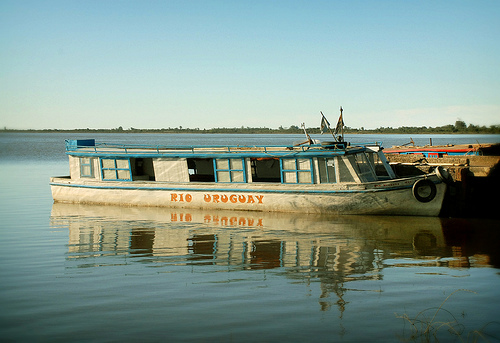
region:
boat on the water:
[40, 111, 460, 236]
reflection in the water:
[58, 202, 374, 289]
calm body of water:
[1, 133, 498, 340]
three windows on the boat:
[122, 153, 285, 186]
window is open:
[98, 158, 163, 182]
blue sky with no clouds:
[1, 1, 499, 128]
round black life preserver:
[410, 173, 446, 209]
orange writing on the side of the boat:
[169, 191, 271, 210]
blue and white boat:
[39, 121, 454, 224]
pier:
[354, 129, 499, 214]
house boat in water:
[4, 147, 435, 223]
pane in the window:
[101, 167, 117, 180]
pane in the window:
[116, 170, 131, 182]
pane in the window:
[116, 158, 130, 169]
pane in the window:
[103, 158, 119, 170]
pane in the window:
[216, 171, 230, 184]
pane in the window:
[213, 159, 227, 171]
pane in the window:
[231, 170, 247, 187]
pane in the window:
[227, 159, 246, 172]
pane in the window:
[285, 170, 303, 185]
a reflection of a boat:
[57, 200, 318, 269]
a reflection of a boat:
[56, 202, 408, 327]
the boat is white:
[39, 122, 443, 236]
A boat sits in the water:
[48, 125, 448, 223]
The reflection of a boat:
[57, 210, 469, 281]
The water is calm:
[41, 217, 381, 338]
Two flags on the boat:
[319, 106, 349, 148]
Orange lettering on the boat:
[165, 190, 268, 207]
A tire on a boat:
[413, 176, 436, 204]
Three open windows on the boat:
[123, 155, 290, 183]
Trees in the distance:
[90, 123, 301, 133]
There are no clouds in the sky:
[15, 51, 280, 101]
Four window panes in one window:
[98, 154, 133, 179]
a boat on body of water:
[41, 98, 451, 221]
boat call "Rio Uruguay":
[42, 97, 452, 222]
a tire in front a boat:
[406, 168, 444, 210]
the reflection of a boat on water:
[50, 213, 391, 308]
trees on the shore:
[0, 118, 497, 137]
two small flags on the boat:
[308, 98, 375, 165]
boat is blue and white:
[37, 123, 454, 224]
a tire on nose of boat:
[425, 148, 467, 191]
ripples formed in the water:
[4, 238, 492, 332]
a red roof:
[373, 134, 483, 156]